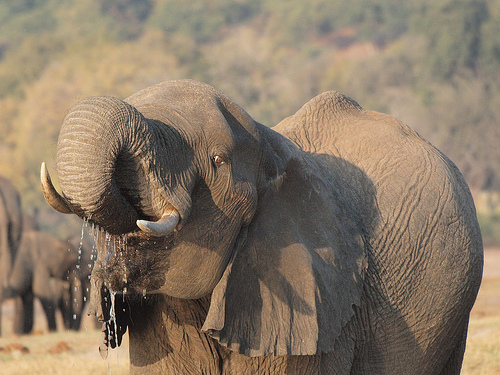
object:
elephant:
[39, 79, 484, 373]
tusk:
[133, 210, 189, 237]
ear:
[200, 168, 370, 359]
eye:
[207, 150, 228, 168]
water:
[75, 217, 135, 355]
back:
[253, 88, 462, 180]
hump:
[297, 87, 363, 121]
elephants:
[4, 180, 42, 335]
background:
[0, 1, 500, 374]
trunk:
[54, 91, 166, 228]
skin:
[384, 157, 442, 218]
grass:
[39, 359, 59, 369]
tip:
[132, 219, 148, 229]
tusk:
[33, 160, 71, 214]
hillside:
[0, 0, 500, 203]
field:
[0, 187, 495, 374]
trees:
[0, 1, 500, 170]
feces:
[47, 342, 74, 359]